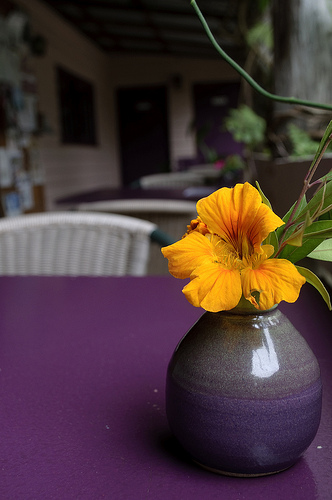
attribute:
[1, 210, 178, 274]
chair — White 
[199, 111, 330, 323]
plant — small, green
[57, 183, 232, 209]
tablecloth — purple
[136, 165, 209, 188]
chair — white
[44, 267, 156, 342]
tablecloth — purple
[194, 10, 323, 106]
wire — green, thin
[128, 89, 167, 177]
door — brown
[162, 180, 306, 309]
flower — beautiful, yellow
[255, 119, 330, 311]
leaves — green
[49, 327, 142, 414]
tablecloth — purple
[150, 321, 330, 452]
vase — purple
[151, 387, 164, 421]
crumbs — small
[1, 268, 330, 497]
tablecloth — purple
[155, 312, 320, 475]
vase — purple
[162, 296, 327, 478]
vase — purple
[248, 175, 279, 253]
leaf — green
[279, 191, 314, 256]
leaf — green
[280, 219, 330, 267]
leaf — green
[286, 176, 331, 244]
leaf — green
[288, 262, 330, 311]
leaf — green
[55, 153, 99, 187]
blank wall — white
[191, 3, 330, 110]
stem — thin, green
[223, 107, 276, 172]
plants — small, green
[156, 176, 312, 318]
flower — yellow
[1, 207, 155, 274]
chair — white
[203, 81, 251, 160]
door — purple 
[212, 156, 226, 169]
flower — pink